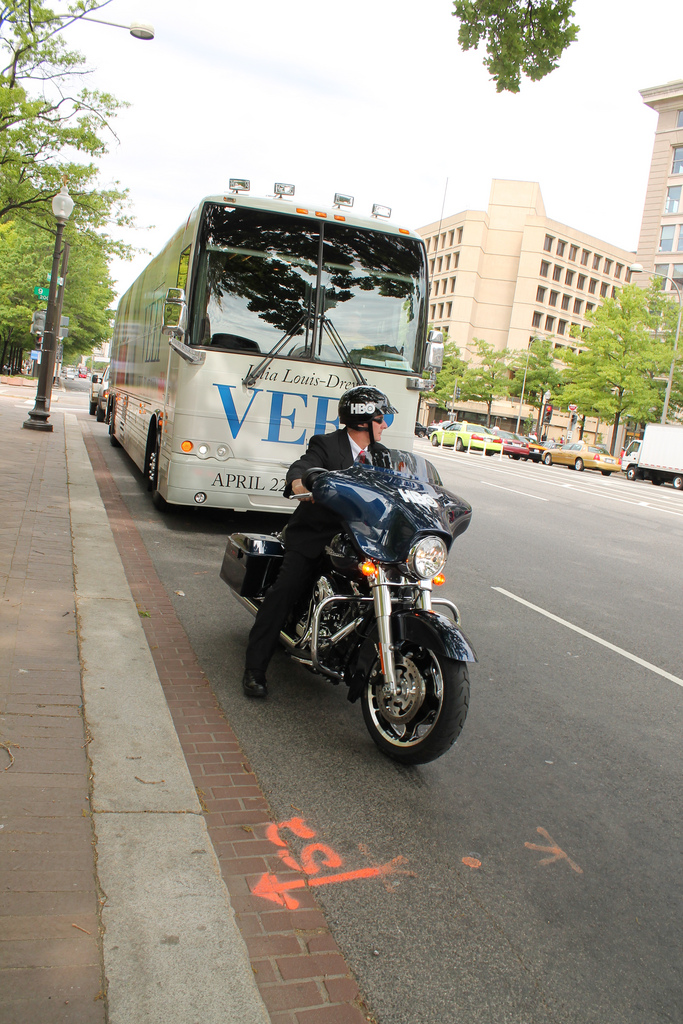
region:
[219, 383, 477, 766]
Man on a motorcycle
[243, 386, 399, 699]
Man wearing a helmit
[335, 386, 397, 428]
HBO is on the helmit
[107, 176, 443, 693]
Bus is behind man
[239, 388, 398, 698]
Man is wearing a suit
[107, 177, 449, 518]
Bus has blue writing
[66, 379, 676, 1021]
White truck on the road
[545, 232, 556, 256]
building has a window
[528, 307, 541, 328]
building has a window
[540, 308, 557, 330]
building has a window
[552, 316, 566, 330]
building has a window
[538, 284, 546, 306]
building has a window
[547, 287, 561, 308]
building has a window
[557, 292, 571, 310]
building has a window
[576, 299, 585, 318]
building has a window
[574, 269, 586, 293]
building has a window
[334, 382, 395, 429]
Black helmet say HBO on it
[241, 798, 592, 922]
Orange paint on the street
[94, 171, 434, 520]
Bus behind the motorcyclist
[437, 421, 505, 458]
Green car on the street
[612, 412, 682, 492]
White truck on the street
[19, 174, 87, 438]
Lamppost on the sidewalk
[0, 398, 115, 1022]
Sidewalk made from brick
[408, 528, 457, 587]
Headlight on motorcycle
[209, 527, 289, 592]
cargo box on motorcycle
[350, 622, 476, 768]
Front wheel of motorcycle